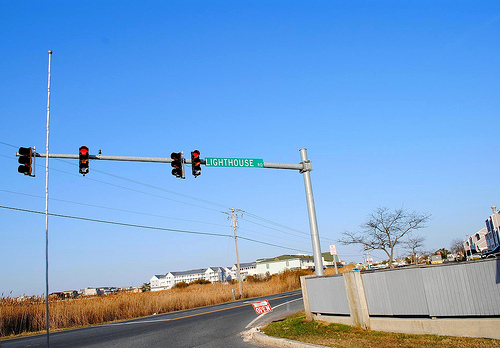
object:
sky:
[0, 0, 500, 303]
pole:
[298, 147, 326, 275]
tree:
[336, 203, 432, 268]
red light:
[79, 147, 86, 156]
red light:
[191, 151, 200, 160]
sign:
[204, 157, 263, 167]